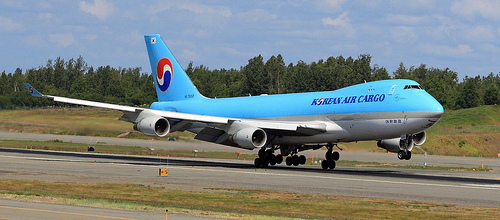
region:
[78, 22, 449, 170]
This is an airplane.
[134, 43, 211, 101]
The symbol is blue, white and red.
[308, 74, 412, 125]
This says Korean Air Cargo.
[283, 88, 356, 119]
This plane is from Korea.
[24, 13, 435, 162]
This plane is light blue and gray.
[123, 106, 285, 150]
These are engines.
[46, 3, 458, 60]
The weather is partly cloudy.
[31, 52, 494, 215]
This is on a runway.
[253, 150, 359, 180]
These are plane wheels.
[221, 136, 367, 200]
The landing gear is down.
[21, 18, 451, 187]
airplane on the runway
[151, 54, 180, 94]
red, white, and blue logo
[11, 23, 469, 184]
light blue and white plane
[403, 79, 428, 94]
windows on the cockpit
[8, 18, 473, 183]
plane about to take off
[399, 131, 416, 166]
front wheels are off the ground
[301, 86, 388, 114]
logo on the side of the plane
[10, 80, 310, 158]
thin airplane wing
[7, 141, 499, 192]
shadow on the runway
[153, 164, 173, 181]
small orange light on the runway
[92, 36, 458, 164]
a blue plane on a runway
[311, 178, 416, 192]
grey tarmac on the runway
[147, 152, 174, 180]
yellow and black sign on the runway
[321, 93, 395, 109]
blue lettering on the plane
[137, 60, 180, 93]
airline logo on the tail fin of the pane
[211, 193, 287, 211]
green grass of the ground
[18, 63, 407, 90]
many trees growing by the runway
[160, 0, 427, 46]
cloudy blue skies over the airport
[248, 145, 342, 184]
the landing geaqr of the plane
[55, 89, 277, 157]
white wing of the plane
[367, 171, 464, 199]
grey tarmac of the runway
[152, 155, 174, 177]
a yellow and black sign on the runway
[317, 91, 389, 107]
blue lettering on the plant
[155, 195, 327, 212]
green grass of the ground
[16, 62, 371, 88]
many green trees in the distance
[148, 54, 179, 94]
airline logo on the tail fin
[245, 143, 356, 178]
landing gear of the plane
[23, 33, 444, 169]
Korean Air cargo plane preparing for take-off.